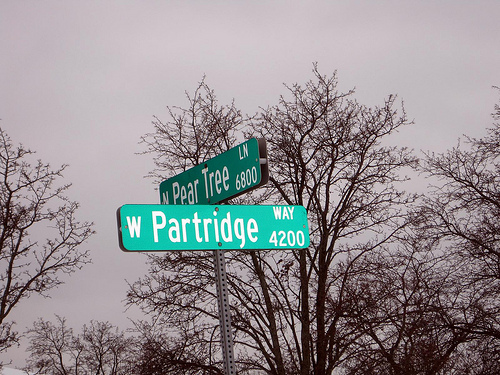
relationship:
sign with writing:
[116, 203, 311, 250] [144, 203, 304, 244]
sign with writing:
[116, 203, 311, 250] [151, 211, 264, 249]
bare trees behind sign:
[228, 62, 433, 375] [116, 203, 311, 250]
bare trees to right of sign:
[312, 90, 499, 360] [116, 203, 311, 250]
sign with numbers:
[116, 203, 311, 250] [268, 230, 306, 247]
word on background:
[268, 200, 310, 224] [116, 202, 310, 252]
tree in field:
[0, 129, 102, 375] [7, 322, 474, 367]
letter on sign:
[126, 215, 140, 242] [116, 203, 311, 250]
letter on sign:
[152, 209, 167, 242] [116, 203, 311, 250]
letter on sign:
[162, 215, 180, 241] [116, 203, 311, 250]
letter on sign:
[219, 210, 236, 242] [116, 203, 311, 250]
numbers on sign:
[267, 227, 308, 248] [116, 203, 311, 250]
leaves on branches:
[341, 101, 437, 152] [314, 127, 382, 266]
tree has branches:
[4, 129, 101, 354] [47, 203, 82, 236]